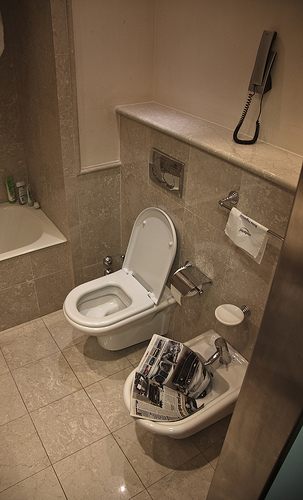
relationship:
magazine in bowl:
[128, 333, 211, 422] [123, 332, 246, 437]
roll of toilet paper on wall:
[168, 264, 214, 301] [118, 114, 298, 364]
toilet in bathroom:
[62, 206, 178, 350] [0, 0, 303, 499]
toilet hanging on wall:
[62, 206, 178, 350] [118, 114, 298, 364]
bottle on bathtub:
[4, 176, 15, 204] [0, 194, 70, 329]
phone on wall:
[235, 29, 278, 146] [72, 3, 302, 168]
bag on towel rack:
[222, 206, 270, 264] [217, 192, 284, 242]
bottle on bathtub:
[17, 181, 24, 204] [0, 194, 70, 329]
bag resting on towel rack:
[222, 206, 270, 264] [217, 192, 284, 242]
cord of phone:
[231, 93, 264, 145] [235, 29, 278, 146]